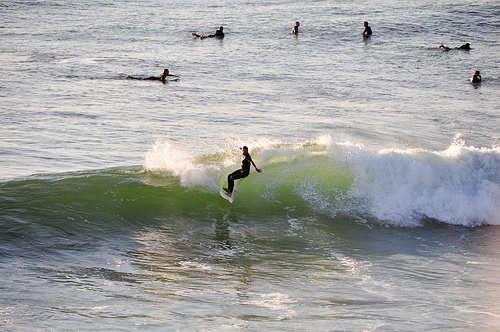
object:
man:
[224, 145, 263, 195]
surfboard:
[219, 179, 234, 208]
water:
[0, 0, 499, 330]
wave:
[341, 141, 495, 227]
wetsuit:
[226, 154, 253, 192]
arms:
[250, 158, 264, 175]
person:
[125, 69, 181, 84]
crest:
[336, 133, 500, 157]